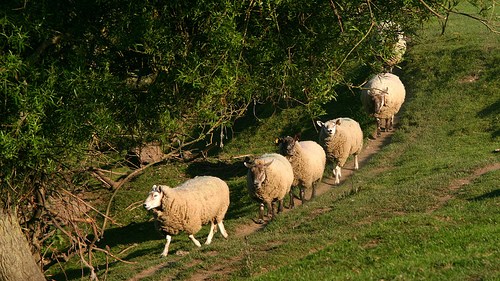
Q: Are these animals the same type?
A: Yes, all the animals are sheep.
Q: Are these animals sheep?
A: Yes, all the animals are sheep.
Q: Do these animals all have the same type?
A: Yes, all the animals are sheep.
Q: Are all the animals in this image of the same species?
A: Yes, all the animals are sheep.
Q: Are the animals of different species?
A: No, all the animals are sheep.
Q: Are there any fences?
A: No, there are no fences.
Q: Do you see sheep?
A: Yes, there is a sheep.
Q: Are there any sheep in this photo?
A: Yes, there is a sheep.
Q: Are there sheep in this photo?
A: Yes, there is a sheep.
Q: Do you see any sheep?
A: Yes, there is a sheep.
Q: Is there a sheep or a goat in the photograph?
A: Yes, there is a sheep.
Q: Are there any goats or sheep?
A: Yes, there is a sheep.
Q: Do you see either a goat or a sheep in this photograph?
A: Yes, there is a sheep.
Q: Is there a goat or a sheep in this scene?
A: Yes, there is a sheep.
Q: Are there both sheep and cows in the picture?
A: No, there is a sheep but no cows.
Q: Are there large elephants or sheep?
A: Yes, there is a large sheep.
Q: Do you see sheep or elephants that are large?
A: Yes, the sheep is large.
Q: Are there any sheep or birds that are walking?
A: Yes, the sheep is walking.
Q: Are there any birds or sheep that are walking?
A: Yes, the sheep is walking.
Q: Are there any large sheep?
A: Yes, there is a large sheep.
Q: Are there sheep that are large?
A: Yes, there is a sheep that is large.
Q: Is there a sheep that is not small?
A: Yes, there is a large sheep.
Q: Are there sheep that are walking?
A: Yes, there is a sheep that is walking.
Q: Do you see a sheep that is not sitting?
A: Yes, there is a sheep that is walking .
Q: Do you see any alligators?
A: No, there are no alligators.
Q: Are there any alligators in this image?
A: No, there are no alligators.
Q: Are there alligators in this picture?
A: No, there are no alligators.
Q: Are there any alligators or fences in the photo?
A: No, there are no alligators or fences.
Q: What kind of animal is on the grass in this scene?
A: The animal is a sheep.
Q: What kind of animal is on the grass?
A: The animal is a sheep.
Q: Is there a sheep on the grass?
A: Yes, there is a sheep on the grass.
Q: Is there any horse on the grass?
A: No, there is a sheep on the grass.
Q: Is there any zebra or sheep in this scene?
A: Yes, there is a sheep.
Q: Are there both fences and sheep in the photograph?
A: No, there is a sheep but no fences.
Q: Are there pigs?
A: No, there are no pigs.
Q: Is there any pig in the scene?
A: No, there are no pigs.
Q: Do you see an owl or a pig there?
A: No, there are no pigs or owls.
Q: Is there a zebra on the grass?
A: No, there is a sheep on the grass.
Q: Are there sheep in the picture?
A: Yes, there is a sheep.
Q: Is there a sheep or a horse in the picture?
A: Yes, there is a sheep.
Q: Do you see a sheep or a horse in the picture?
A: Yes, there is a sheep.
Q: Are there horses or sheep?
A: Yes, there is a sheep.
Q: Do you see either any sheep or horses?
A: Yes, there is a sheep.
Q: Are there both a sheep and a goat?
A: No, there is a sheep but no goats.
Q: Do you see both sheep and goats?
A: No, there is a sheep but no goats.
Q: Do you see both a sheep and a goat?
A: No, there is a sheep but no goats.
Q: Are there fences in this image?
A: No, there are no fences.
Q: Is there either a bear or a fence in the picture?
A: No, there are no fences or bears.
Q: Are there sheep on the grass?
A: Yes, there is a sheep on the grass.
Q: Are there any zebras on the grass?
A: No, there is a sheep on the grass.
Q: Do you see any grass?
A: Yes, there is grass.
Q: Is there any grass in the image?
A: Yes, there is grass.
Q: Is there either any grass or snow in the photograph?
A: Yes, there is grass.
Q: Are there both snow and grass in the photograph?
A: No, there is grass but no snow.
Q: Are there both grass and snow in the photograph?
A: No, there is grass but no snow.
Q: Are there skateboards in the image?
A: No, there are no skateboards.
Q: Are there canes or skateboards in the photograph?
A: No, there are no skateboards or canes.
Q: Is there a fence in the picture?
A: No, there are no fences.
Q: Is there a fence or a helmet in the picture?
A: No, there are no fences or helmets.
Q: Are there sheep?
A: Yes, there is a sheep.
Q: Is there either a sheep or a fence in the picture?
A: Yes, there is a sheep.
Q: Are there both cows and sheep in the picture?
A: No, there is a sheep but no cows.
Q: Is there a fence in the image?
A: No, there are no fences.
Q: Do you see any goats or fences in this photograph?
A: No, there are no fences or goats.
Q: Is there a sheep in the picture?
A: Yes, there is a sheep.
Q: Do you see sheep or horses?
A: Yes, there is a sheep.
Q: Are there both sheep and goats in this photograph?
A: No, there is a sheep but no goats.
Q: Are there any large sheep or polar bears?
A: Yes, there is a large sheep.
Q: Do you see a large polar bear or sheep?
A: Yes, there is a large sheep.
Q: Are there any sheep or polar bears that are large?
A: Yes, the sheep is large.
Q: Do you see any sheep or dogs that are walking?
A: Yes, the sheep is walking.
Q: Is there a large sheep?
A: Yes, there is a large sheep.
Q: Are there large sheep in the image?
A: Yes, there is a large sheep.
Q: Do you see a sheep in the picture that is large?
A: Yes, there is a sheep that is large.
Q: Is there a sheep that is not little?
A: Yes, there is a large sheep.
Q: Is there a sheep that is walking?
A: Yes, there is a sheep that is walking.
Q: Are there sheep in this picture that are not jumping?
A: Yes, there is a sheep that is walking.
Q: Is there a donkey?
A: No, there are no donkeys.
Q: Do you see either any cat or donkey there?
A: No, there are no donkeys or cats.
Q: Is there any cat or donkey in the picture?
A: No, there are no donkeys or cats.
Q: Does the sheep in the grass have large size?
A: Yes, the sheep is large.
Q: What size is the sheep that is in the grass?
A: The sheep is large.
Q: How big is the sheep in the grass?
A: The sheep is large.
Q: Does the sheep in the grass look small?
A: No, the sheep is large.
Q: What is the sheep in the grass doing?
A: The sheep is walking.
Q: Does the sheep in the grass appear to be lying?
A: No, the sheep is walking.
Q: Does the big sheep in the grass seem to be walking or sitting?
A: The sheep is walking.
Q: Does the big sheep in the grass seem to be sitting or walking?
A: The sheep is walking.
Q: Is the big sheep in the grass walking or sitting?
A: The sheep is walking.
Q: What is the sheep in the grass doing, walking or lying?
A: The sheep is walking.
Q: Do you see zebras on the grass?
A: No, there is a sheep on the grass.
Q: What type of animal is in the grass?
A: The animal is a sheep.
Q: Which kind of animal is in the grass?
A: The animal is a sheep.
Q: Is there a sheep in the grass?
A: Yes, there is a sheep in the grass.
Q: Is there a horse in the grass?
A: No, there is a sheep in the grass.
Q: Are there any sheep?
A: Yes, there is a sheep.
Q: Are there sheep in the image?
A: Yes, there is a sheep.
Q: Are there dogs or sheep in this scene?
A: Yes, there is a sheep.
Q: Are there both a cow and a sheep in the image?
A: No, there is a sheep but no cows.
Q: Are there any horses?
A: No, there are no horses.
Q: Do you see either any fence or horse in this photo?
A: No, there are no horses or fences.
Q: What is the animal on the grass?
A: The animal is a sheep.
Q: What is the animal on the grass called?
A: The animal is a sheep.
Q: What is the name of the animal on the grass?
A: The animal is a sheep.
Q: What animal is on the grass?
A: The animal is a sheep.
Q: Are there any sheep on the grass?
A: Yes, there is a sheep on the grass.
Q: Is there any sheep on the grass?
A: Yes, there is a sheep on the grass.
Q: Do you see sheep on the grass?
A: Yes, there is a sheep on the grass.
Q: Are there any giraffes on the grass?
A: No, there is a sheep on the grass.